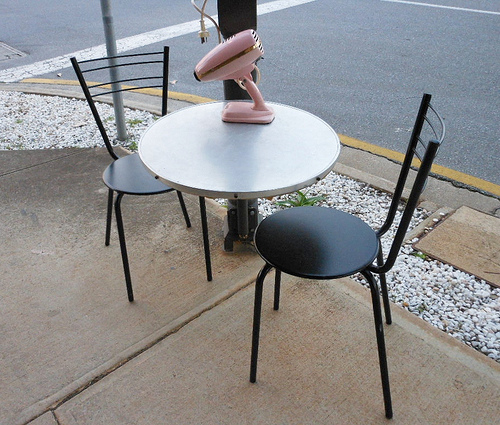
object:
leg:
[109, 190, 136, 310]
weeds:
[278, 187, 328, 208]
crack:
[0, 278, 258, 422]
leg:
[369, 282, 396, 422]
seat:
[102, 150, 162, 197]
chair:
[68, 44, 214, 306]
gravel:
[376, 258, 498, 363]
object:
[194, 28, 275, 126]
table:
[134, 98, 345, 200]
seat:
[250, 204, 381, 282]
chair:
[245, 91, 445, 421]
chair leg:
[197, 197, 213, 283]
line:
[0, 0, 312, 88]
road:
[0, 0, 499, 186]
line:
[416, 153, 499, 202]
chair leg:
[250, 263, 273, 387]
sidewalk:
[0, 145, 498, 422]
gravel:
[0, 88, 101, 155]